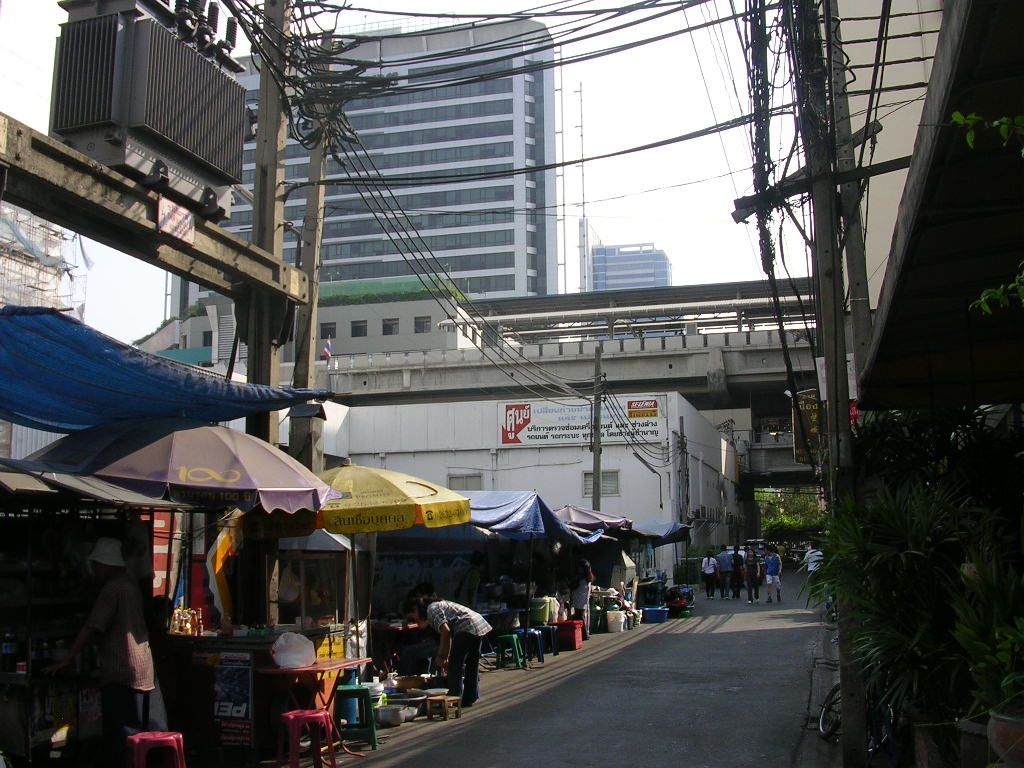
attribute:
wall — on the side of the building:
[388, 35, 503, 53]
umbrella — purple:
[87, 428, 330, 526]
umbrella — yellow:
[312, 454, 462, 545]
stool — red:
[273, 700, 340, 757]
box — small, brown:
[418, 681, 501, 746]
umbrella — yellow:
[291, 450, 469, 539]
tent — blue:
[440, 482, 583, 565]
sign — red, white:
[511, 405, 686, 451]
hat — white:
[46, 517, 153, 593]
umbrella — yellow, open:
[319, 435, 443, 529]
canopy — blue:
[344, 431, 448, 527]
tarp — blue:
[59, 294, 224, 415]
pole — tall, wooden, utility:
[217, 72, 405, 459]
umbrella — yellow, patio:
[314, 469, 462, 573]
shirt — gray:
[403, 567, 490, 643]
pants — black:
[438, 631, 534, 731]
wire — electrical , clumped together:
[250, 12, 404, 147]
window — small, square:
[412, 299, 458, 345]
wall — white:
[357, 292, 446, 383]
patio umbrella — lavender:
[18, 381, 360, 531]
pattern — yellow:
[152, 450, 254, 494]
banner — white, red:
[484, 387, 688, 465]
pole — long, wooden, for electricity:
[271, 63, 336, 509]